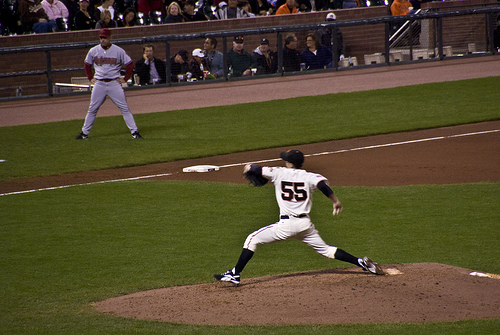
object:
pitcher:
[212, 149, 383, 285]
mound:
[91, 263, 500, 326]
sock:
[235, 248, 255, 275]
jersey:
[281, 181, 308, 202]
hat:
[279, 148, 305, 168]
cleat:
[213, 267, 241, 285]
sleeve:
[317, 180, 334, 197]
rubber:
[383, 267, 404, 275]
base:
[182, 165, 219, 173]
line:
[0, 130, 500, 195]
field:
[0, 56, 499, 334]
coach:
[75, 28, 144, 140]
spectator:
[135, 44, 167, 85]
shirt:
[84, 44, 133, 80]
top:
[390, 0, 412, 17]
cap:
[99, 28, 113, 38]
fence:
[0, 6, 500, 101]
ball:
[332, 208, 340, 216]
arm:
[316, 180, 337, 204]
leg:
[235, 222, 290, 274]